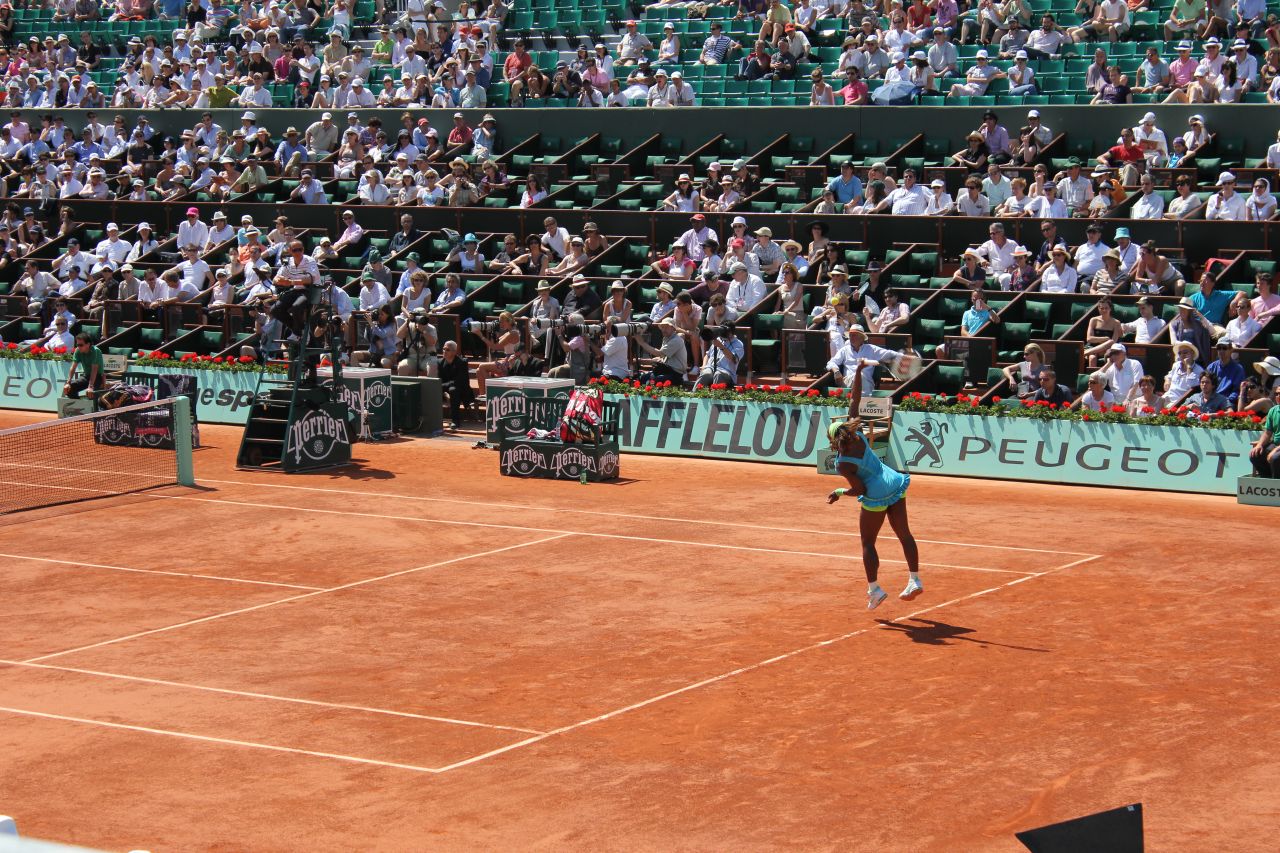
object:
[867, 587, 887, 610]
shoe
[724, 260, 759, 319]
man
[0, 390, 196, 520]
net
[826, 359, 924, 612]
man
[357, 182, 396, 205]
shirt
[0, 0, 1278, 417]
spectators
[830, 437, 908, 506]
blue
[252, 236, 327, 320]
chair umpire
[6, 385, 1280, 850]
tennis court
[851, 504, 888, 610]
leg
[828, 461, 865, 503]
arm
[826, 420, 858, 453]
head